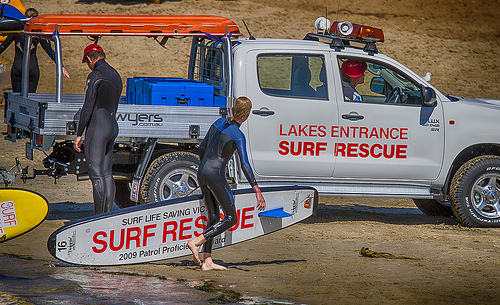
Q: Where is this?
A: This is at the beach.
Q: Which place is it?
A: It is a beach.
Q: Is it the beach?
A: Yes, it is the beach.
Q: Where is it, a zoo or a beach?
A: It is a beach.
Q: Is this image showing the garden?
A: No, the picture is showing the beach.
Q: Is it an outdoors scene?
A: Yes, it is outdoors.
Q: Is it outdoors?
A: Yes, it is outdoors.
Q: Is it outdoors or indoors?
A: It is outdoors.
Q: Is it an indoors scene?
A: No, it is outdoors.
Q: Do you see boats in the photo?
A: No, there are no boats.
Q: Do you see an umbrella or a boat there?
A: No, there are no boats or umbrellas.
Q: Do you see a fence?
A: No, there are no fences.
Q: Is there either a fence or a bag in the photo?
A: No, there are no fences or bags.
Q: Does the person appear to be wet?
A: Yes, the person is wet.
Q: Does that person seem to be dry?
A: No, the person is wet.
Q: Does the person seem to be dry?
A: No, the person is wet.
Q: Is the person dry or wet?
A: The person is wet.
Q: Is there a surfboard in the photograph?
A: Yes, there is a surfboard.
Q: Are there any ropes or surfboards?
A: Yes, there is a surfboard.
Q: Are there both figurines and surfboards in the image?
A: No, there is a surfboard but no figurines.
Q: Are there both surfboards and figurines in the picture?
A: No, there is a surfboard but no figurines.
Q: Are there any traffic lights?
A: No, there are no traffic lights.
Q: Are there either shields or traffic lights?
A: No, there are no traffic lights or shields.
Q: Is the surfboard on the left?
A: Yes, the surfboard is on the left of the image.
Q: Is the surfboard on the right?
A: No, the surfboard is on the left of the image.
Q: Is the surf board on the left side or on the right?
A: The surf board is on the left of the image.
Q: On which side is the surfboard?
A: The surfboard is on the left of the image.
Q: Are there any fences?
A: No, there are no fences.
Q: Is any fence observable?
A: No, there are no fences.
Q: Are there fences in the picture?
A: No, there are no fences.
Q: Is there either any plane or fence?
A: No, there are no fences or airplanes.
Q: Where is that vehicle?
A: The vehicle is on the beach.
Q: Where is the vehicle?
A: The vehicle is on the beach.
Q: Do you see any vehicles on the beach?
A: Yes, there is a vehicle on the beach.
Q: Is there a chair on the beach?
A: No, there is a vehicle on the beach.